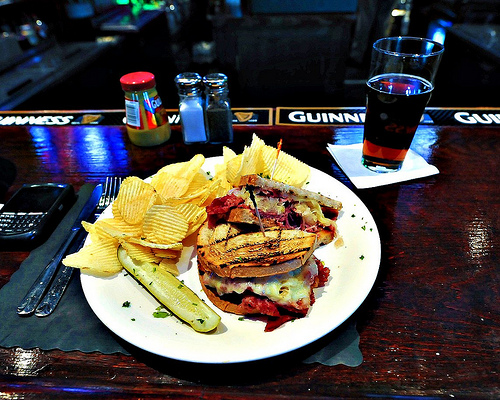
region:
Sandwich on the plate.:
[187, 215, 329, 325]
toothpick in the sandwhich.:
[239, 178, 270, 237]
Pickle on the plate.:
[112, 232, 224, 339]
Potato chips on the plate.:
[67, 135, 312, 281]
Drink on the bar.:
[354, 25, 445, 175]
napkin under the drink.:
[325, 133, 442, 193]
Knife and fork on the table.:
[15, 170, 128, 318]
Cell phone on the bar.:
[1, 171, 77, 249]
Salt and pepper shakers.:
[172, 65, 234, 147]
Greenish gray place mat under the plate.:
[0, 160, 364, 372]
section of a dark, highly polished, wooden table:
[0, 124, 497, 399]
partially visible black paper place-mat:
[0, 181, 363, 367]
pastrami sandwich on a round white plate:
[79, 152, 381, 361]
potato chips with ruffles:
[62, 132, 307, 274]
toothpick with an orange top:
[271, 137, 281, 177]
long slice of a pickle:
[115, 242, 221, 334]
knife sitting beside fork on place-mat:
[0, 174, 121, 354]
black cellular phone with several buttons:
[0, 176, 74, 245]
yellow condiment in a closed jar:
[121, 71, 171, 147]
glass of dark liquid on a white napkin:
[325, 36, 445, 190]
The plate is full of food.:
[60, 132, 380, 364]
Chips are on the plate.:
[122, 178, 194, 228]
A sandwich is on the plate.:
[197, 225, 327, 293]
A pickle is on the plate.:
[150, 273, 181, 303]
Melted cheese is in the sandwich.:
[262, 277, 302, 299]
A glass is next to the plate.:
[362, 35, 441, 171]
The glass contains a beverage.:
[360, 75, 431, 170]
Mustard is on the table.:
[121, 69, 171, 148]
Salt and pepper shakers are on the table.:
[176, 71, 231, 143]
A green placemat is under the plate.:
[12, 319, 89, 347]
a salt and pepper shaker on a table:
[177, 72, 232, 145]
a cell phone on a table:
[2, 178, 70, 243]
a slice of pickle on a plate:
[116, 243, 220, 333]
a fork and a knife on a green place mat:
[20, 175, 125, 317]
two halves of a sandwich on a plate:
[196, 170, 344, 331]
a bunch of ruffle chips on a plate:
[62, 130, 304, 273]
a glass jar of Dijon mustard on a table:
[121, 71, 170, 149]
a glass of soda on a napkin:
[362, 36, 442, 178]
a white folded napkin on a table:
[327, 138, 440, 188]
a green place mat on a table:
[0, 182, 363, 369]